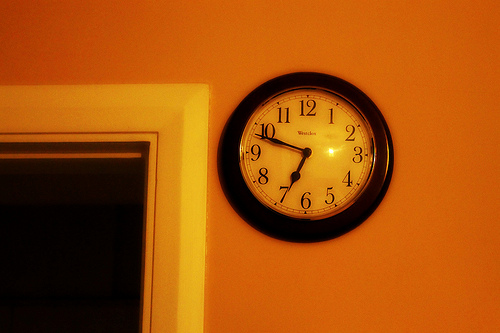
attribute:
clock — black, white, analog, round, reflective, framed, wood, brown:
[217, 71, 393, 244]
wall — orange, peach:
[1, 1, 499, 333]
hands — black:
[254, 133, 313, 192]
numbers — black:
[249, 96, 364, 210]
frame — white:
[237, 88, 372, 218]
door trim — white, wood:
[2, 81, 212, 332]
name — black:
[296, 130, 318, 137]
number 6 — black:
[297, 189, 313, 212]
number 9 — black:
[248, 140, 264, 162]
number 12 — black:
[298, 98, 318, 117]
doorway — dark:
[0, 143, 146, 332]